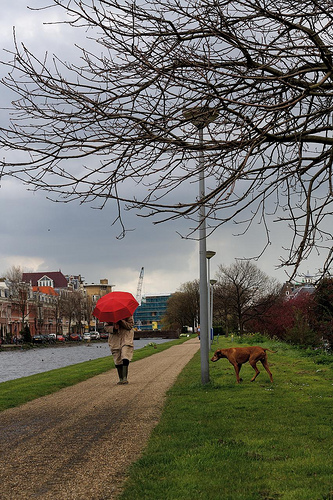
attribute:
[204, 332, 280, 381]
dog — brown, sniffing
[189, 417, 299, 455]
grass — green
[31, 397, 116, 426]
sidewalk — long, gravel, dirt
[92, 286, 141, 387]
man — walking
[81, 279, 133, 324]
umbrella — red, bright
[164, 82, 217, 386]
pole — tall, grey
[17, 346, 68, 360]
river — water, narrow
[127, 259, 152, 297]
crane — downtown, tall, distant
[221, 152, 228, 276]
tree — tall, no leaves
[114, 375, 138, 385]
boots — black, tall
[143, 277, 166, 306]
ladder — tall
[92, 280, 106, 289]
rooftop — red, orange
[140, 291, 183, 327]
building — multistory, under construction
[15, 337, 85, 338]
vehicles — parked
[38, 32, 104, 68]
sky — overcast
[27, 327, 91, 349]
cars — parked